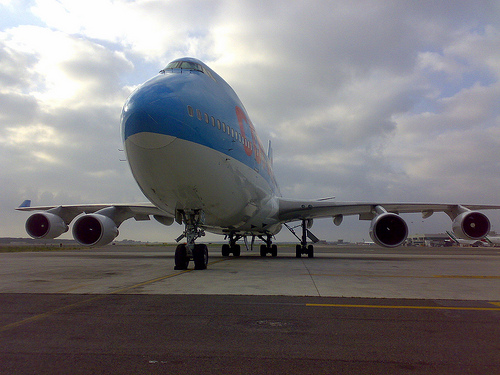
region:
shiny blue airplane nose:
[117, 82, 189, 157]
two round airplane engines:
[361, 200, 491, 252]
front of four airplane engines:
[22, 203, 493, 250]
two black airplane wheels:
[169, 234, 212, 274]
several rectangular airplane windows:
[184, 98, 274, 158]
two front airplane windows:
[158, 53, 207, 74]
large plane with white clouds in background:
[21, 18, 495, 269]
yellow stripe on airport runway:
[290, 289, 499, 325]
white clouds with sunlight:
[9, 12, 116, 174]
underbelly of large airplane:
[118, 136, 263, 207]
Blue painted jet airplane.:
[115, 57, 285, 197]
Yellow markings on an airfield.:
[294, 286, 498, 338]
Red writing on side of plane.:
[237, 106, 293, 186]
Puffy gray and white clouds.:
[267, 22, 499, 83]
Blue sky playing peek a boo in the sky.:
[417, 100, 442, 110]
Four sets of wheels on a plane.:
[167, 243, 316, 268]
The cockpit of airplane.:
[157, 56, 214, 76]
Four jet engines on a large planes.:
[23, 209, 493, 250]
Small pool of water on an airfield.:
[145, 350, 182, 374]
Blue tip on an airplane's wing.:
[19, 198, 32, 213]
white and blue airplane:
[96, 56, 286, 262]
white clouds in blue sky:
[10, 3, 94, 66]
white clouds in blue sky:
[3, 60, 110, 136]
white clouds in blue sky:
[30, 125, 107, 188]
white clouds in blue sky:
[80, 21, 140, 49]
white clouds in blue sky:
[172, 11, 252, 42]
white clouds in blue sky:
[243, 14, 376, 90]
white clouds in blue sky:
[267, 67, 340, 151]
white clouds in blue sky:
[340, 6, 462, 72]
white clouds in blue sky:
[338, 78, 418, 149]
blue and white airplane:
[35, 59, 473, 279]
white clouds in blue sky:
[12, 12, 77, 60]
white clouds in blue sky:
[19, 61, 94, 121]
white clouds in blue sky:
[21, 114, 91, 161]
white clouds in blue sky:
[83, 16, 137, 61]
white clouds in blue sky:
[215, 6, 293, 54]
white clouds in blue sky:
[289, 95, 346, 152]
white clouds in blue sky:
[286, 134, 354, 188]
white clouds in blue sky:
[365, 132, 450, 179]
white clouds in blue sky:
[353, 19, 448, 117]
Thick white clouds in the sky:
[253, 10, 386, 127]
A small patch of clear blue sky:
[435, 78, 458, 94]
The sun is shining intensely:
[14, 2, 123, 84]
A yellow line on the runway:
[306, 296, 489, 325]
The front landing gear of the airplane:
[172, 205, 216, 274]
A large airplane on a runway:
[20, 58, 485, 359]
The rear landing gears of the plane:
[222, 236, 319, 263]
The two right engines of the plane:
[23, 209, 130, 254]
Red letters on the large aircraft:
[232, 113, 279, 181]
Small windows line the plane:
[182, 116, 284, 148]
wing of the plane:
[279, 153, 466, 279]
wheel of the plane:
[138, 208, 232, 293]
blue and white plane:
[28, 45, 407, 309]